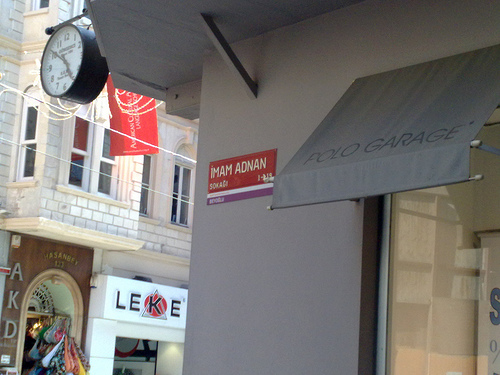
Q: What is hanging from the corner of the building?
A: Clock.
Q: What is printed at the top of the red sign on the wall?
A: Imam Adnan.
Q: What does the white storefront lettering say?
A: Leke.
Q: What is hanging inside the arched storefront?
A: Bags.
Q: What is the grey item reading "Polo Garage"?
A: Canopy.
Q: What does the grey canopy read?
A: Polo Garage.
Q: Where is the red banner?
A: Behind clock.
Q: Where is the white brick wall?
A: Above stores.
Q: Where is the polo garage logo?
A: On the canopy.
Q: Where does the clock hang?
A: On the side of a grey building.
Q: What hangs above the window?
A: A gray awning.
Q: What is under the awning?
A: A glass door.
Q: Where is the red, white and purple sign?
A: On the grey building.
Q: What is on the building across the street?
A: A red flag.